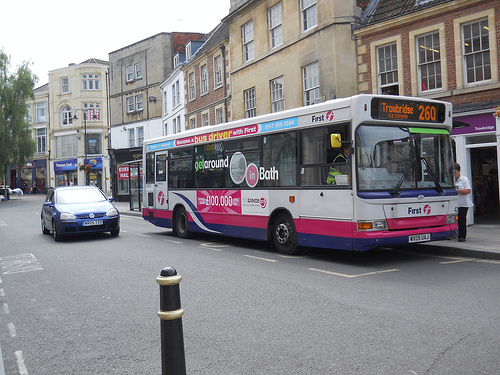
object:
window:
[266, 3, 284, 50]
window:
[242, 21, 254, 61]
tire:
[272, 212, 306, 255]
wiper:
[389, 159, 416, 196]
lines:
[11, 351, 31, 375]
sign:
[54, 157, 103, 170]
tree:
[0, 52, 33, 202]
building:
[3, 57, 108, 193]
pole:
[153, 265, 188, 375]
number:
[418, 104, 437, 121]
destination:
[382, 103, 414, 114]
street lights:
[72, 115, 78, 119]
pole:
[84, 121, 87, 149]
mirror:
[330, 133, 342, 148]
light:
[358, 222, 372, 229]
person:
[455, 163, 475, 242]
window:
[299, 122, 351, 190]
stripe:
[171, 192, 222, 234]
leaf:
[8, 151, 15, 158]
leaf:
[0, 152, 7, 160]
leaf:
[22, 145, 27, 152]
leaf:
[17, 132, 24, 137]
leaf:
[7, 92, 14, 109]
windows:
[263, 131, 296, 187]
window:
[126, 65, 134, 81]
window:
[135, 62, 143, 77]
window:
[128, 97, 135, 111]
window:
[136, 94, 143, 109]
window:
[129, 129, 135, 148]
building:
[105, 31, 204, 202]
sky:
[0, 0, 225, 67]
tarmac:
[118, 229, 474, 278]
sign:
[196, 190, 242, 214]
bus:
[140, 93, 461, 255]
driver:
[327, 146, 350, 184]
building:
[357, 0, 499, 230]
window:
[376, 41, 399, 87]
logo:
[408, 204, 432, 215]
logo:
[195, 155, 229, 172]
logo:
[260, 166, 279, 180]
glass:
[356, 126, 417, 190]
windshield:
[353, 121, 455, 189]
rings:
[156, 273, 183, 285]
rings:
[157, 307, 185, 321]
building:
[221, 0, 359, 119]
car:
[40, 185, 120, 241]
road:
[1, 268, 500, 375]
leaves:
[0, 80, 11, 89]